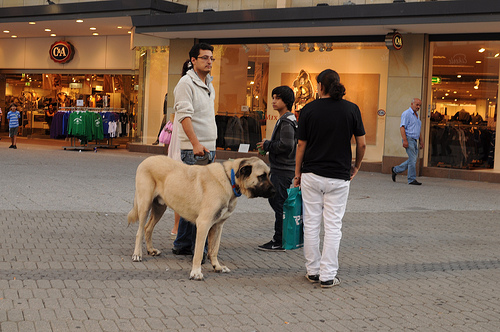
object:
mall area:
[4, 146, 497, 332]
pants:
[295, 169, 351, 285]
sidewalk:
[0, 144, 500, 332]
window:
[218, 44, 278, 166]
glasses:
[195, 56, 216, 62]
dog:
[126, 153, 276, 280]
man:
[6, 105, 22, 150]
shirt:
[7, 110, 21, 128]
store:
[4, 35, 140, 144]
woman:
[291, 67, 365, 288]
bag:
[280, 185, 302, 251]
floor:
[0, 133, 493, 330]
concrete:
[4, 133, 497, 212]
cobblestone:
[4, 211, 500, 331]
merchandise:
[67, 110, 86, 136]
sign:
[49, 40, 75, 64]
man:
[170, 38, 221, 257]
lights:
[325, 42, 334, 52]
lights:
[75, 19, 85, 24]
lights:
[477, 47, 487, 55]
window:
[69, 71, 131, 128]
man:
[391, 97, 424, 186]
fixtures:
[392, 28, 398, 33]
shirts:
[98, 110, 111, 139]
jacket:
[264, 112, 301, 172]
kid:
[257, 83, 300, 252]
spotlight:
[241, 43, 251, 53]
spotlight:
[281, 43, 291, 53]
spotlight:
[306, 42, 314, 53]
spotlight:
[298, 42, 306, 52]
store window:
[208, 39, 385, 161]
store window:
[429, 40, 494, 169]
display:
[288, 68, 317, 121]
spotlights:
[261, 44, 271, 52]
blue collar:
[228, 158, 242, 198]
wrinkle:
[303, 200, 321, 210]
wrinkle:
[325, 209, 340, 215]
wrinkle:
[322, 224, 340, 233]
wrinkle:
[302, 232, 317, 241]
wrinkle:
[324, 196, 342, 209]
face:
[198, 48, 215, 73]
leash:
[200, 146, 240, 199]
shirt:
[294, 97, 365, 180]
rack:
[224, 116, 245, 148]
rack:
[49, 112, 62, 139]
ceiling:
[0, 12, 135, 40]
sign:
[385, 31, 404, 50]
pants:
[266, 167, 298, 245]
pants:
[394, 135, 421, 184]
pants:
[172, 146, 216, 253]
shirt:
[397, 109, 427, 141]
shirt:
[171, 69, 221, 151]